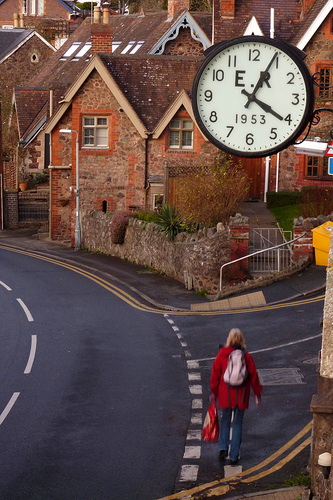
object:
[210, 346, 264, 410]
coat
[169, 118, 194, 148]
window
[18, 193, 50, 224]
brick steps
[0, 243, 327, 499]
road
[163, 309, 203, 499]
dotted line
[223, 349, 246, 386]
backpack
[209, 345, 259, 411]
jacket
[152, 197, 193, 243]
tree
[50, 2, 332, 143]
roofs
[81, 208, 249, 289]
fence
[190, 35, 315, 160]
clock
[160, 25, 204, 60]
border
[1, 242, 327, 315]
line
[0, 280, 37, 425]
line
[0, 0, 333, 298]
houses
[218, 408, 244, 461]
jeans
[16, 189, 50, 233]
stairs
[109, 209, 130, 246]
vines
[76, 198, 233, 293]
wall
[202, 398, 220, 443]
bag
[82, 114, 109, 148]
window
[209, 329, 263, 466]
woman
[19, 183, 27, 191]
flowerpot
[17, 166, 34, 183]
plant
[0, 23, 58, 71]
roof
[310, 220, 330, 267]
trash receptacle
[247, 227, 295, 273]
gate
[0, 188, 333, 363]
hilltop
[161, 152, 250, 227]
partition